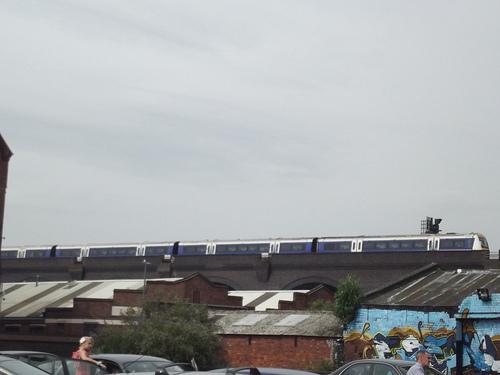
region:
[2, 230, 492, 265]
train riding on bridge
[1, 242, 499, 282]
bridge holding the train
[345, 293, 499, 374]
grafitti on front wall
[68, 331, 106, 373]
woman standing beside car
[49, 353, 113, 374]
passenger car door is open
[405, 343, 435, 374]
man standing in front of car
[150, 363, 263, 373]
luggage rack on car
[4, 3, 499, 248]
sky is very cloudy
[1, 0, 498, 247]
sky is very gray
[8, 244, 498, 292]
bridge is black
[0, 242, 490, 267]
a long train on rails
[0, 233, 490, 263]
the train is white and blue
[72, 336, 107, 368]
a man wears a hat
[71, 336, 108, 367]
a man wears a sleeveless shirt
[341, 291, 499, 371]
graffiti on the building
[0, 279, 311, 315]
the roof is white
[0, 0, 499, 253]
the sky is overcast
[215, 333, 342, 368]
the building is made of bricks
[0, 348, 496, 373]
a parking lot outdoors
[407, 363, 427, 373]
a man wears a gray shirt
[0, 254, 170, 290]
staduim seats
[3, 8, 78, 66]
white and gray colored clouds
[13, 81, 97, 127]
white and gray colored clouds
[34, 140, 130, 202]
white and gray colored clouds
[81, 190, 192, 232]
white and gray colored clouds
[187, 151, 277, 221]
white and gray colored clouds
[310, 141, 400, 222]
white and gray colored clouds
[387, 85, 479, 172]
white and gray colored clouds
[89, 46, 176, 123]
white and gray colored clouds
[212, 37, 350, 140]
white and gray colored clouds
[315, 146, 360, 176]
part of a cloud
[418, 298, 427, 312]
part of a roof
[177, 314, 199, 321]
part of a tree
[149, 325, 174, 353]
part of a bush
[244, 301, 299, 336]
edge of a roof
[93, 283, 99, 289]
top of a roof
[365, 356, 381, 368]
part of a window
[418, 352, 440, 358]
head of a man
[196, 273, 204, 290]
part of a building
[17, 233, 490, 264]
Blue and white train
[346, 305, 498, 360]
Painting on a wall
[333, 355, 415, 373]
Top of a car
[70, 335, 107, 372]
Woman standing outside of a car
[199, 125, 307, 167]
Cloud covered sky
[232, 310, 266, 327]
White square on top of a building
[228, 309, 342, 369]
Red building with white roof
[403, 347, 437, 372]
Man standing by car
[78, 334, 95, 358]
Woman with a white flower in her hair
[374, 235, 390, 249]
Window on a train car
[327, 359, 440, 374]
the side of a car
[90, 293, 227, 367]
a large green tree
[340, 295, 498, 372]
a graffiti painted wall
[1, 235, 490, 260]
a long blue and white train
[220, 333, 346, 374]
the side of a red brick building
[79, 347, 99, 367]
the arm of a man